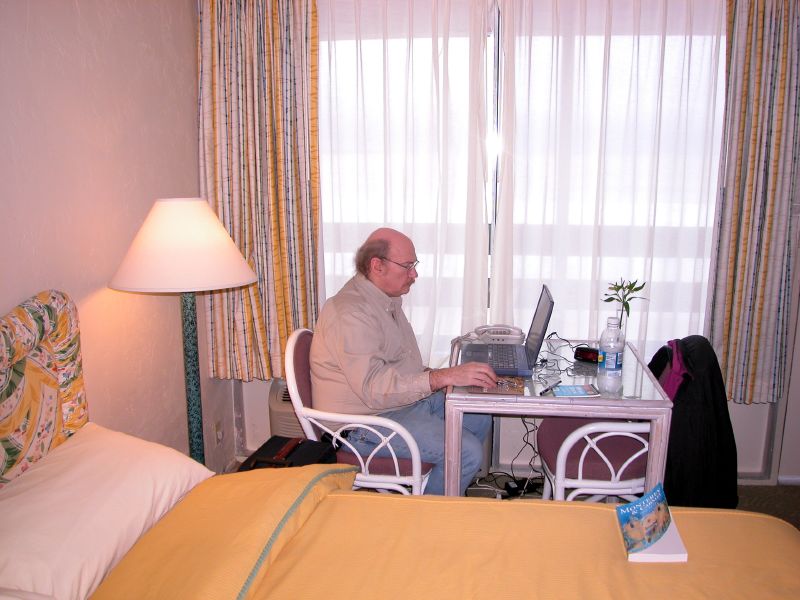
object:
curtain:
[702, 0, 800, 405]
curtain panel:
[196, 0, 326, 382]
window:
[196, 0, 800, 406]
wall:
[0, 0, 242, 473]